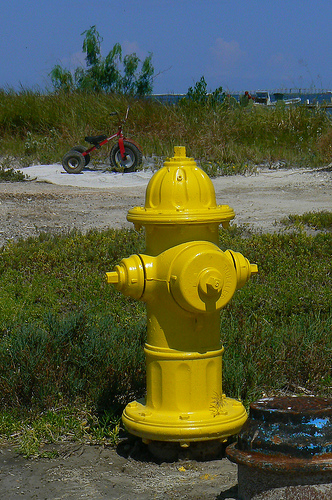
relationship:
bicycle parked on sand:
[56, 115, 148, 175] [42, 167, 140, 190]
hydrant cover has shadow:
[123, 139, 235, 225] [140, 223, 220, 245]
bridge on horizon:
[263, 87, 330, 101] [9, 85, 331, 105]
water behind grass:
[157, 90, 185, 98] [3, 85, 331, 165]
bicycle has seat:
[56, 115, 148, 175] [82, 131, 106, 145]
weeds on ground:
[0, 306, 147, 420] [0, 85, 321, 499]